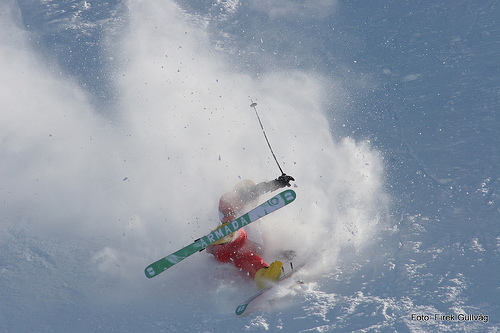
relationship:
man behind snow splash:
[208, 172, 298, 288] [2, 1, 387, 332]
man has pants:
[208, 172, 298, 288] [205, 228, 266, 274]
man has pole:
[208, 172, 298, 288] [248, 96, 297, 177]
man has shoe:
[208, 172, 298, 288] [254, 262, 282, 289]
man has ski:
[208, 172, 298, 288] [142, 186, 296, 287]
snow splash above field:
[2, 1, 387, 332] [5, 2, 495, 330]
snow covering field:
[2, 3, 495, 332] [5, 2, 495, 330]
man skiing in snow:
[208, 172, 298, 288] [2, 3, 495, 332]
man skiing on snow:
[208, 172, 298, 288] [2, 3, 495, 332]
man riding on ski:
[208, 172, 298, 288] [142, 186, 296, 287]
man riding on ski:
[208, 172, 298, 288] [233, 245, 307, 313]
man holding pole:
[208, 172, 298, 288] [248, 96, 297, 177]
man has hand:
[208, 172, 298, 288] [276, 173, 295, 189]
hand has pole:
[276, 173, 295, 189] [248, 96, 297, 177]